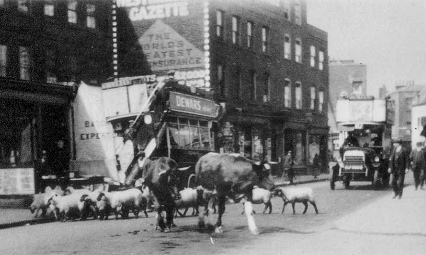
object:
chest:
[223, 175, 254, 203]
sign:
[168, 90, 220, 118]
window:
[18, 43, 32, 80]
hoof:
[249, 230, 260, 235]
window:
[216, 9, 223, 37]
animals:
[27, 152, 319, 236]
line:
[307, 227, 426, 236]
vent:
[343, 156, 365, 172]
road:
[0, 172, 425, 254]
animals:
[272, 186, 318, 214]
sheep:
[96, 188, 148, 219]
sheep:
[46, 192, 95, 215]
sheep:
[26, 192, 58, 218]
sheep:
[235, 188, 275, 215]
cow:
[194, 152, 282, 236]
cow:
[142, 152, 282, 235]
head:
[158, 166, 191, 200]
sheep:
[27, 183, 317, 231]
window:
[318, 49, 324, 70]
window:
[294, 36, 303, 64]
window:
[261, 26, 268, 53]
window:
[246, 21, 252, 48]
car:
[327, 100, 406, 195]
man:
[386, 138, 410, 199]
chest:
[155, 185, 170, 205]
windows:
[215, 10, 324, 116]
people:
[409, 134, 426, 191]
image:
[116, 2, 204, 72]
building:
[0, 0, 330, 207]